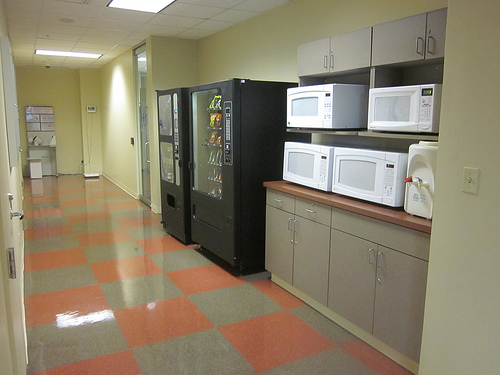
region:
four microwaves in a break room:
[270, 66, 499, 233]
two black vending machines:
[141, 58, 301, 295]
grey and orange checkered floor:
[43, 238, 245, 368]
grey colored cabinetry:
[269, 219, 399, 297]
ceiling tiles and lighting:
[19, 3, 124, 72]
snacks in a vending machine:
[183, 73, 277, 278]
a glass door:
[104, 27, 170, 214]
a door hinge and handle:
[0, 180, 38, 373]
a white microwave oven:
[273, 74, 379, 134]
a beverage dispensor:
[387, 131, 448, 234]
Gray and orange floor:
[26, 173, 421, 373]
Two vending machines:
[155, 77, 272, 277]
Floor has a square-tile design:
[35, 175, 450, 370]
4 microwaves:
[285, 75, 440, 220]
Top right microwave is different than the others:
[280, 75, 440, 220]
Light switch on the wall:
[456, 155, 488, 214]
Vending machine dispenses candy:
[186, 73, 274, 275]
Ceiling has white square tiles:
[0, 2, 305, 73]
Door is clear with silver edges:
[116, 43, 164, 213]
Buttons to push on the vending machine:
[219, 101, 236, 172]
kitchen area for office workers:
[48, 48, 464, 356]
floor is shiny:
[46, 269, 188, 344]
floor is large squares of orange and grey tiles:
[49, 237, 296, 357]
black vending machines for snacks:
[152, 75, 259, 277]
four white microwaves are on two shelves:
[277, 65, 444, 217]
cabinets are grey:
[243, 174, 415, 359]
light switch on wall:
[451, 140, 485, 208]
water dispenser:
[402, 137, 432, 223]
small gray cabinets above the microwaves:
[275, 14, 452, 74]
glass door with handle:
[107, 60, 158, 207]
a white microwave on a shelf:
[279, 80, 367, 132]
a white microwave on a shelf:
[359, 81, 438, 134]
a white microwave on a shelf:
[281, 136, 332, 196]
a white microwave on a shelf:
[329, 139, 406, 211]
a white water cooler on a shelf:
[399, 135, 439, 225]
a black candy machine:
[184, 71, 303, 276]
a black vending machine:
[152, 82, 192, 247]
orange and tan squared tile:
[14, 165, 394, 367]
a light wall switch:
[458, 159, 483, 201]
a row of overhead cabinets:
[287, 2, 448, 79]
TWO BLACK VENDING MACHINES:
[150, 74, 307, 286]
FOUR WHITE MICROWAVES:
[275, 79, 445, 210]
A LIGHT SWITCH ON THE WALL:
[457, 162, 482, 199]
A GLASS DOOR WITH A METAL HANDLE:
[125, 35, 162, 215]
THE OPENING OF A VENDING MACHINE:
[161, 190, 181, 212]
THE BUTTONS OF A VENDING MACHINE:
[215, 92, 239, 174]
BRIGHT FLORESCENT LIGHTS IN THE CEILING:
[30, 42, 107, 69]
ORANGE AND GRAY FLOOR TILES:
[15, 162, 427, 373]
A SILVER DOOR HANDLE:
[6, 205, 31, 226]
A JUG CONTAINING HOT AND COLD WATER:
[396, 136, 446, 227]